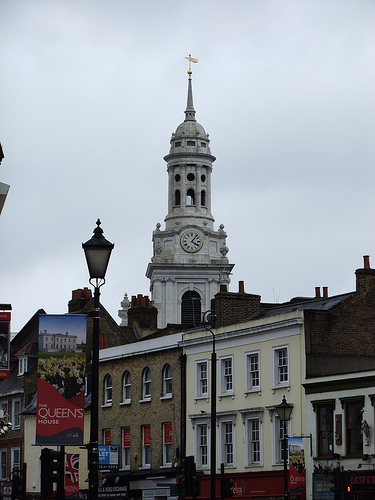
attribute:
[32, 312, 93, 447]
sign — blue 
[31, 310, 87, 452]
queens — red 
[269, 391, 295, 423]
lamp — Black 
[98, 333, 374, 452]
building — white 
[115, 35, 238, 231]
tower — gray, white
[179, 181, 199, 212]
window — arched, white 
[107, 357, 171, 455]
building — brown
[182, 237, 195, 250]
numerals — roman